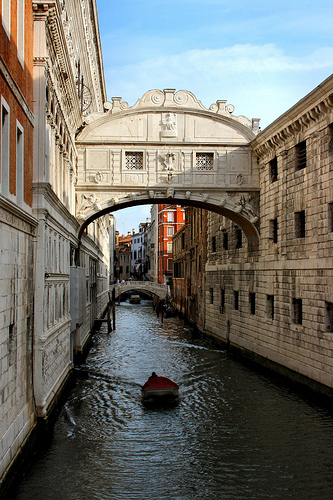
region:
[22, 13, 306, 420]
a canal in venice, Italy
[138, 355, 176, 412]
a small boat on a canal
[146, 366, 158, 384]
a man driving a small boat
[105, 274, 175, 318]
a bridge over a canal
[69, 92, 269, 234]
an ornate covered bridge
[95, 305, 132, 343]
a small dock on a canal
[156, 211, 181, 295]
a building painted red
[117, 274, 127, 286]
two people crossing a bridge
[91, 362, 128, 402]
the wake of a boat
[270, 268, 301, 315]
water stains on a brick wall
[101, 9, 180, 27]
clear patch of blue sky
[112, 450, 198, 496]
murky dark water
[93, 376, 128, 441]
ripples in water caused by motion of boat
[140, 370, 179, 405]
boat going between two buildings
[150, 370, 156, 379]
person driving boat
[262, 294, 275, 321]
window for seeing out/in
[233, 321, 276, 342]
bricks making up building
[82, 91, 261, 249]
archway connecting two buildings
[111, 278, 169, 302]
low bridge in distance for people crossing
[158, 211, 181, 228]
bright orange/red building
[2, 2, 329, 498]
A river runs through the city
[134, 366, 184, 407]
a boat in the river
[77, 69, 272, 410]
a bridge on top the river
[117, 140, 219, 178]
two windows on the bridge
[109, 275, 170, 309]
a boat pass under a bridge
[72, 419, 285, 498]
ripples in the water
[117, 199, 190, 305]
a red building behind a bridge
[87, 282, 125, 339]
two poles on side the building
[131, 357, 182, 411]
a person in the boat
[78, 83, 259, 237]
the bridge is color white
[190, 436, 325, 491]
A still grey water surface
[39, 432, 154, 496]
A still grey water surface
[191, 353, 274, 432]
A still grey water surface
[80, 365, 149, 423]
A still grey water surface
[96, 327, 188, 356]
A still grey water surface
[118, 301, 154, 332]
A still grey water surface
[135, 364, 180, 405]
A small white and red boat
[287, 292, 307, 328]
A small building wall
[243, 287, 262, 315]
A small building wall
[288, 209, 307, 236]
A small building wall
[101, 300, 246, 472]
water way between buildings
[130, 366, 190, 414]
boat in the water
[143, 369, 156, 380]
person on the boat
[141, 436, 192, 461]
ripples in the water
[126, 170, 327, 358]
buildings on side of water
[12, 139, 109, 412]
buildings on side of water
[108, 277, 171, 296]
bridge at end of water way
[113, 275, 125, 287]
person on the bridge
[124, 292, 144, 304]
boat under the bridge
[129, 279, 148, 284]
railing on the bridge